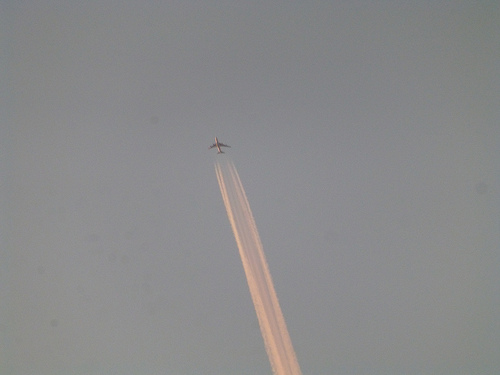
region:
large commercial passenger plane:
[205, 127, 234, 156]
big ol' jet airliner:
[209, 131, 234, 156]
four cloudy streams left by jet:
[210, 145, 305, 373]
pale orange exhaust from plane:
[208, 155, 308, 372]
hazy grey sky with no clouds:
[0, 0, 498, 374]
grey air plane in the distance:
[200, 134, 232, 159]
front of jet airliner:
[209, 135, 221, 140]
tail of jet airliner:
[211, 147, 228, 156]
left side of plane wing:
[219, 139, 229, 150]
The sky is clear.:
[73, 112, 130, 180]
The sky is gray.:
[28, 72, 106, 157]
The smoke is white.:
[204, 174, 311, 372]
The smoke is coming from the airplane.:
[215, 162, 307, 370]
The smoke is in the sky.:
[214, 160, 303, 373]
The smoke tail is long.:
[211, 162, 304, 369]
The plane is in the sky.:
[206, 130, 233, 162]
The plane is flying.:
[206, 132, 234, 160]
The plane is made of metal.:
[204, 137, 232, 156]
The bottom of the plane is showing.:
[206, 130, 232, 162]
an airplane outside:
[161, 74, 321, 245]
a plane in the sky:
[172, 113, 286, 223]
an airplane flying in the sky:
[209, 135, 269, 180]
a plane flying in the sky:
[140, 106, 306, 210]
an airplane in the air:
[179, 106, 242, 213]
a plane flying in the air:
[209, 131, 247, 188]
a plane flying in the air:
[204, 106, 273, 199]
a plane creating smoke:
[194, 102, 436, 372]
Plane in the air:
[203, 130, 230, 157]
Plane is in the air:
[203, 129, 234, 156]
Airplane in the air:
[205, 127, 235, 158]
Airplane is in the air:
[201, 131, 235, 158]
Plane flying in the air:
[205, 131, 228, 158]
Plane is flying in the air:
[205, 130, 235, 156]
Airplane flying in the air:
[205, 132, 235, 157]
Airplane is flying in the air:
[204, 132, 234, 157]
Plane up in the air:
[205, 128, 235, 156]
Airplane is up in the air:
[204, 130, 233, 157]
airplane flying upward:
[186, 113, 307, 369]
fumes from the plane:
[191, 160, 316, 371]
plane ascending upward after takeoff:
[173, 140, 316, 370]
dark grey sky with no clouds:
[11, 6, 488, 362]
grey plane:
[207, 126, 230, 156]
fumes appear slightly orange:
[195, 158, 306, 369]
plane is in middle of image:
[205, 123, 233, 158]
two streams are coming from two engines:
[207, 161, 313, 371]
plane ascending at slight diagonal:
[195, 133, 346, 369]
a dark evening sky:
[7, 18, 491, 365]